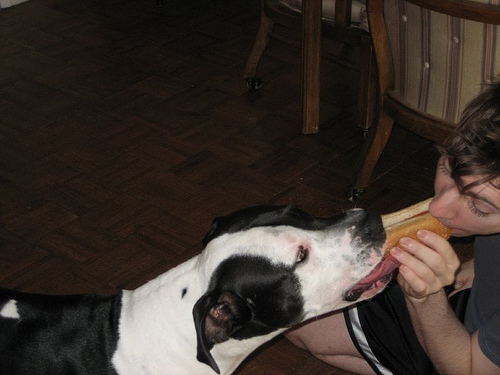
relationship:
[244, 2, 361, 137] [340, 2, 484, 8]
chair next to a table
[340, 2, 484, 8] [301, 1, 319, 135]
table has a leg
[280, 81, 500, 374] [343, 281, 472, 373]
man has on shorts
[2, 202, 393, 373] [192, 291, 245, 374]
dog has an ear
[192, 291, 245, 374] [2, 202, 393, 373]
ear on a dog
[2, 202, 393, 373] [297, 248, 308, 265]
dog has an eye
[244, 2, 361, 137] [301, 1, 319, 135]
chair has a leg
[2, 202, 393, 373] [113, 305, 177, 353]
dog has fur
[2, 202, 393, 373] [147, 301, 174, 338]
dog has white fur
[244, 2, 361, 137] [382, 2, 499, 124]
chair has a back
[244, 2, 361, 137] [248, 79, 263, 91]
chair has a coaster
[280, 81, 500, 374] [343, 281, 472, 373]
man wearing shorts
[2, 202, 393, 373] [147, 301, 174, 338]
dog inside white fur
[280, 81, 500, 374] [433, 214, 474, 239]
man has a mouth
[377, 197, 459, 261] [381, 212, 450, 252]
bun on a bun